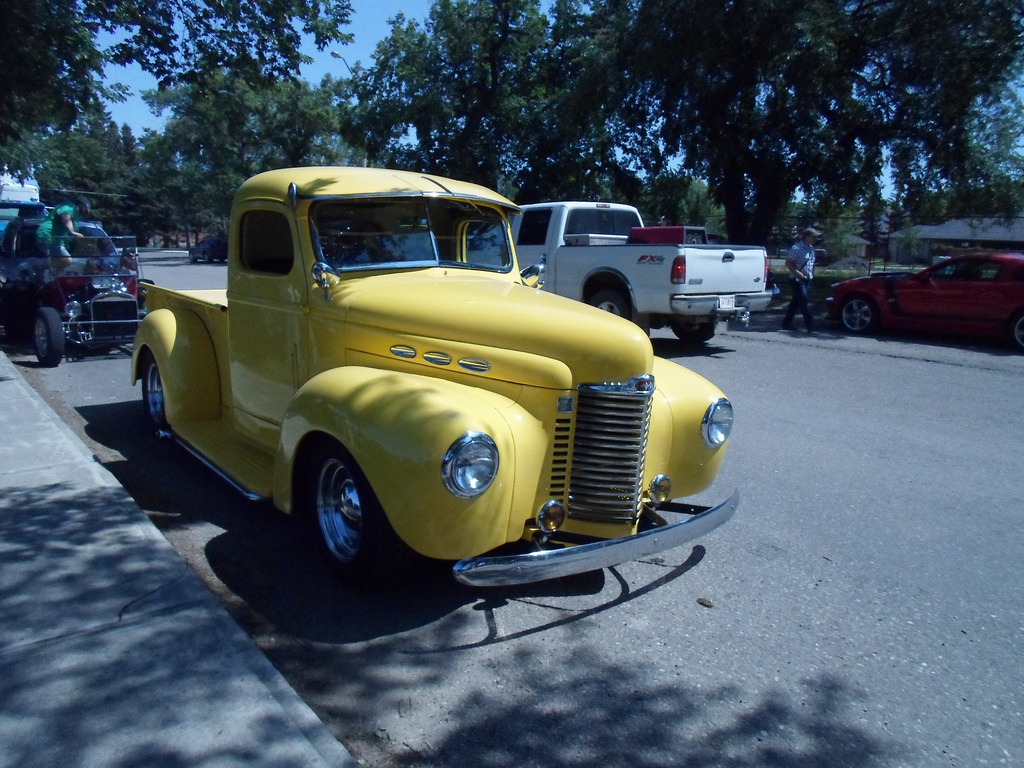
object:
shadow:
[0, 474, 918, 768]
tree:
[0, 1, 359, 192]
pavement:
[2, 255, 1024, 765]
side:
[829, 250, 983, 332]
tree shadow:
[0, 480, 450, 764]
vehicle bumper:
[452, 487, 744, 591]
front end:
[27, 235, 156, 366]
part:
[449, 487, 742, 589]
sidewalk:
[0, 351, 357, 768]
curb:
[145, 505, 363, 768]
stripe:
[844, 273, 1024, 328]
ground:
[501, 629, 1024, 768]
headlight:
[437, 429, 502, 503]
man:
[781, 224, 824, 338]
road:
[761, 298, 963, 420]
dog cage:
[623, 224, 711, 247]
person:
[32, 193, 91, 279]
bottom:
[831, 293, 1022, 345]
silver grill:
[565, 372, 658, 527]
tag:
[714, 307, 750, 328]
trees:
[35, 103, 139, 209]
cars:
[775, 233, 870, 259]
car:
[187, 217, 230, 267]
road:
[123, 235, 933, 300]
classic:
[129, 163, 746, 597]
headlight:
[700, 393, 737, 453]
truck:
[503, 198, 776, 346]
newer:
[695, 274, 734, 281]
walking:
[770, 310, 826, 336]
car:
[0, 201, 157, 371]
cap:
[800, 227, 821, 238]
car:
[828, 250, 1024, 353]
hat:
[75, 193, 94, 214]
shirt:
[785, 240, 818, 283]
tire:
[295, 435, 387, 588]